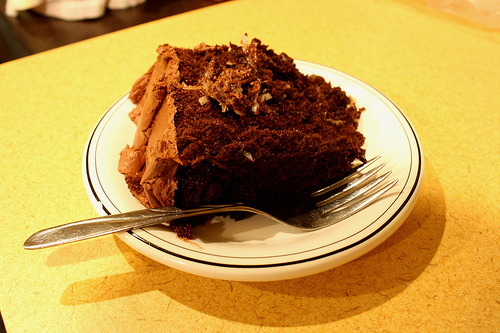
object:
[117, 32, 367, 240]
cake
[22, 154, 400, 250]
fork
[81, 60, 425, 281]
plate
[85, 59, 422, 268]
ring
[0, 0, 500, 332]
table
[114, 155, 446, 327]
shadow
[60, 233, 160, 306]
shadow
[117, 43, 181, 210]
frosting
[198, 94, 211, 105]
piece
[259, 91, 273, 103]
piece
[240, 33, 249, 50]
piece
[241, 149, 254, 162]
piece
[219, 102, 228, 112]
piece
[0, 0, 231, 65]
floor